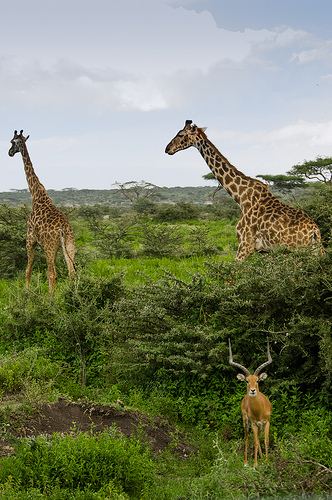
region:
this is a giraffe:
[145, 116, 328, 291]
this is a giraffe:
[0, 127, 97, 295]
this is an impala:
[199, 309, 291, 487]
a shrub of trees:
[103, 274, 238, 421]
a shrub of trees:
[64, 423, 155, 497]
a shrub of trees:
[190, 443, 240, 498]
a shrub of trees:
[50, 287, 123, 402]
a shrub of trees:
[282, 399, 319, 493]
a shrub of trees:
[137, 213, 184, 288]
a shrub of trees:
[185, 200, 236, 285]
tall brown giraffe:
[6, 125, 83, 287]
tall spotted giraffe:
[144, 115, 283, 251]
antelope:
[218, 338, 287, 454]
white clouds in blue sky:
[5, 9, 42, 62]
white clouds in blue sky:
[43, 6, 88, 70]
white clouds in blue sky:
[2, 40, 54, 84]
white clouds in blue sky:
[42, 108, 85, 149]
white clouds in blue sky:
[96, 118, 132, 156]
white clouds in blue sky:
[170, 63, 220, 118]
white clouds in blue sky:
[230, 45, 276, 99]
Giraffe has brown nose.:
[162, 145, 179, 175]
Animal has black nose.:
[249, 384, 265, 403]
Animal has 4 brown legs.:
[221, 419, 275, 462]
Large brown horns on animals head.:
[234, 364, 278, 373]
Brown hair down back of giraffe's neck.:
[197, 126, 266, 209]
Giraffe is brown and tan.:
[219, 169, 293, 250]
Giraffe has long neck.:
[20, 146, 54, 211]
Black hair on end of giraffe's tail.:
[66, 250, 86, 274]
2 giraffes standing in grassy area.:
[18, 192, 304, 275]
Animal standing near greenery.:
[219, 418, 307, 498]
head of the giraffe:
[140, 115, 217, 170]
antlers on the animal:
[221, 333, 285, 374]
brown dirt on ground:
[116, 412, 152, 444]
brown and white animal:
[220, 357, 292, 441]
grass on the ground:
[197, 453, 238, 486]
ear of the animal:
[259, 367, 274, 384]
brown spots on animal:
[246, 206, 286, 232]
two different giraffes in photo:
[2, 88, 315, 289]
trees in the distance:
[98, 177, 174, 211]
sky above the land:
[65, 17, 156, 89]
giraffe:
[5, 127, 76, 270]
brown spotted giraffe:
[158, 111, 324, 254]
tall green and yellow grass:
[109, 247, 149, 280]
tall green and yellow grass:
[144, 393, 201, 425]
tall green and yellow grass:
[170, 215, 209, 270]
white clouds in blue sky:
[12, 8, 72, 58]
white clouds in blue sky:
[43, 76, 99, 133]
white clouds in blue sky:
[86, 129, 132, 165]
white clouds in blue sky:
[117, 34, 172, 110]